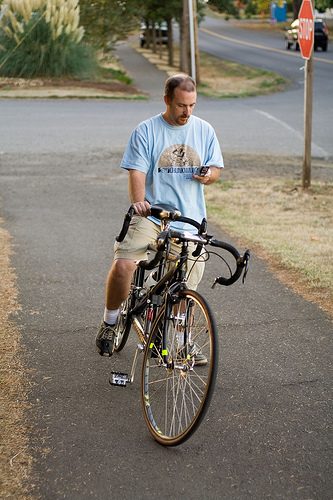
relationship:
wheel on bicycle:
[141, 289, 219, 448] [109, 204, 250, 447]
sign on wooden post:
[293, 5, 320, 65] [299, 62, 315, 190]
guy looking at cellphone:
[96, 74, 225, 366] [198, 166, 210, 177]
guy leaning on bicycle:
[96, 74, 225, 366] [109, 203, 250, 447]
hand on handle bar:
[133, 201, 152, 218] [117, 197, 252, 285]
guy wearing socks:
[96, 74, 225, 366] [99, 296, 130, 333]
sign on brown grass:
[297, 1, 314, 60] [205, 154, 332, 315]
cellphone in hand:
[196, 163, 206, 175] [192, 166, 220, 184]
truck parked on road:
[129, 13, 181, 44] [200, 17, 322, 154]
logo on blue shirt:
[157, 142, 202, 172] [120, 110, 225, 232]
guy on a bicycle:
[96, 74, 225, 366] [109, 204, 250, 447]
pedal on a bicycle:
[107, 371, 129, 387] [94, 201, 255, 447]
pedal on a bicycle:
[169, 306, 189, 327] [94, 201, 255, 447]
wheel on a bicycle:
[134, 285, 224, 448] [54, 178, 287, 470]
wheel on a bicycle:
[98, 257, 144, 356] [54, 178, 287, 470]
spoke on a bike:
[143, 373, 175, 384] [114, 201, 249, 449]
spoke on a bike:
[172, 371, 186, 425] [114, 201, 249, 449]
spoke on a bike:
[183, 373, 209, 378] [114, 201, 249, 449]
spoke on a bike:
[186, 340, 208, 358] [114, 201, 249, 449]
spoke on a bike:
[184, 297, 194, 341] [114, 201, 249, 449]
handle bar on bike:
[115, 202, 250, 290] [96, 204, 252, 446]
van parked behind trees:
[140, 25, 169, 47] [130, 0, 196, 85]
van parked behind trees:
[154, 23, 159, 45] [130, 0, 196, 85]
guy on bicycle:
[96, 73, 223, 365] [109, 203, 250, 447]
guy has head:
[96, 74, 225, 366] [162, 74, 196, 124]